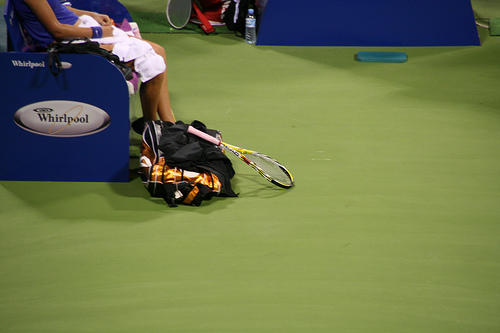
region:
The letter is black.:
[35, 110, 48, 125]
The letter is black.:
[45, 106, 52, 121]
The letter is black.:
[51, 105, 57, 125]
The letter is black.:
[56, 110, 61, 125]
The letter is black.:
[60, 105, 65, 125]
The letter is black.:
[65, 110, 72, 125]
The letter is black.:
[70, 110, 75, 125]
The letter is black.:
[76, 110, 82, 120]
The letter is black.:
[80, 107, 90, 122]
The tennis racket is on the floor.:
[138, 101, 353, 237]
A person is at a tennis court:
[15, 6, 485, 321]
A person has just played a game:
[22, 2, 483, 328]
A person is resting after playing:
[21, 1, 468, 327]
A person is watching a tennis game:
[20, 1, 470, 327]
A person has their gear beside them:
[20, 6, 492, 327]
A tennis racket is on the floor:
[40, 12, 462, 327]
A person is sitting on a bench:
[0, 7, 486, 327]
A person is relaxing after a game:
[16, 5, 301, 226]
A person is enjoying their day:
[7, 0, 347, 240]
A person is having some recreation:
[0, 1, 320, 239]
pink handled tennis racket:
[178, 123, 303, 192]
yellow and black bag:
[134, 113, 239, 208]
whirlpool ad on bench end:
[8, 96, 115, 146]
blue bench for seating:
[0, 3, 150, 193]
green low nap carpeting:
[2, 0, 498, 328]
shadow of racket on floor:
[226, 163, 286, 203]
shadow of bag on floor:
[0, 173, 243, 231]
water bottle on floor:
[237, 5, 260, 48]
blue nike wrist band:
[87, 21, 103, 43]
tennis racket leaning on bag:
[180, 118, 298, 195]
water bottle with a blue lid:
[244, 8, 255, 44]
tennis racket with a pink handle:
[187, 125, 295, 189]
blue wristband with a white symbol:
[88, 25, 103, 38]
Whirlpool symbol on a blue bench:
[11, 98, 111, 137]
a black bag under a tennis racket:
[141, 117, 240, 206]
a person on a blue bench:
[13, 1, 180, 126]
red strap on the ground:
[190, 2, 213, 34]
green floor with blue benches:
[2, 1, 497, 330]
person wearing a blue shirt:
[13, 0, 178, 128]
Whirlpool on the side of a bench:
[8, 58, 70, 72]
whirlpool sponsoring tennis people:
[14, 100, 110, 138]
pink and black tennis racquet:
[186, 125, 295, 190]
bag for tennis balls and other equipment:
[141, 117, 241, 206]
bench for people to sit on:
[0, 51, 139, 183]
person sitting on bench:
[23, 0, 174, 120]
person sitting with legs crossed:
[128, 36, 180, 129]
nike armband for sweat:
[87, 24, 108, 40]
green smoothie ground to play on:
[309, 75, 490, 329]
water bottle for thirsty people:
[245, 10, 259, 40]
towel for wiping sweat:
[78, 20, 157, 85]